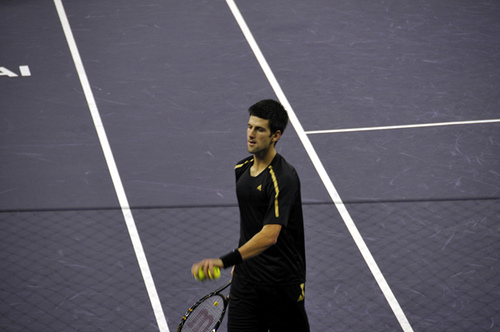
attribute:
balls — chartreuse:
[176, 248, 290, 308]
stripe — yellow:
[259, 168, 286, 224]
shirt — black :
[236, 160, 308, 291]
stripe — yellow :
[251, 161, 298, 227]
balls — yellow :
[196, 224, 237, 292]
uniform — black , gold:
[162, 149, 378, 307]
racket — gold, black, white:
[130, 237, 251, 327]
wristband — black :
[202, 236, 262, 274]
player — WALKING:
[178, 95, 328, 317]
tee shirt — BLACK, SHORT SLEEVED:
[235, 154, 301, 283]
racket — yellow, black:
[182, 282, 235, 329]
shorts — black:
[228, 300, 313, 330]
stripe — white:
[297, 123, 420, 330]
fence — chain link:
[2, 191, 497, 330]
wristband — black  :
[222, 245, 245, 268]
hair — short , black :
[246, 93, 290, 143]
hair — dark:
[247, 94, 288, 147]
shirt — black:
[229, 153, 311, 279]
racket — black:
[175, 281, 231, 331]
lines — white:
[54, 1, 497, 330]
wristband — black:
[219, 249, 243, 268]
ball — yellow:
[203, 263, 224, 282]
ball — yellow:
[193, 263, 203, 283]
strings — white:
[181, 293, 224, 330]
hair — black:
[247, 96, 287, 134]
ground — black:
[1, 1, 497, 328]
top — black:
[220, 153, 306, 287]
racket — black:
[165, 270, 231, 328]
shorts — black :
[178, 271, 333, 323]